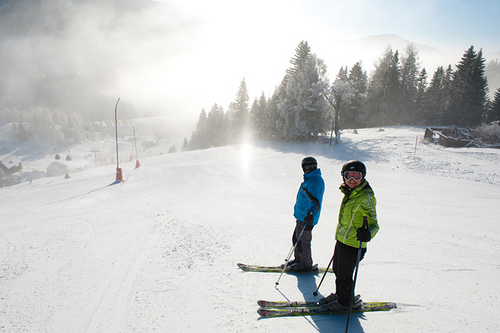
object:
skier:
[281, 156, 326, 273]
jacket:
[293, 166, 326, 225]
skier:
[319, 158, 381, 312]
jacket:
[335, 178, 380, 248]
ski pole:
[274, 221, 307, 287]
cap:
[301, 156, 319, 171]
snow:
[0, 124, 499, 332]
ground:
[0, 124, 499, 330]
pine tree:
[265, 39, 340, 142]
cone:
[116, 167, 126, 184]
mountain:
[0, 32, 500, 186]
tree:
[363, 46, 403, 128]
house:
[0, 153, 26, 176]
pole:
[114, 96, 124, 184]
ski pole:
[345, 214, 369, 332]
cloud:
[0, 0, 500, 124]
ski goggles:
[342, 170, 364, 182]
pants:
[332, 239, 367, 307]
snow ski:
[257, 304, 393, 318]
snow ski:
[256, 300, 397, 308]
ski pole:
[312, 253, 335, 297]